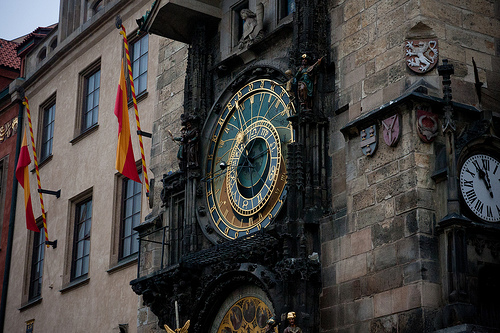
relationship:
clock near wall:
[190, 57, 306, 244] [337, 166, 420, 295]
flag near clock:
[86, 74, 160, 183] [190, 57, 306, 244]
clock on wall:
[190, 57, 306, 244] [337, 166, 420, 295]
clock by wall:
[190, 57, 306, 244] [337, 166, 420, 295]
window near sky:
[59, 65, 112, 142] [8, 2, 44, 22]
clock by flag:
[190, 57, 306, 244] [86, 74, 160, 183]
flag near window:
[86, 74, 160, 183] [59, 65, 112, 142]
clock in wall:
[190, 57, 306, 244] [337, 166, 420, 295]